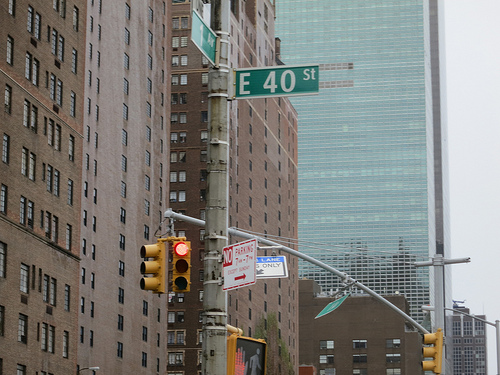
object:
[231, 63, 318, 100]
sign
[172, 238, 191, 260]
light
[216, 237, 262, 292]
sign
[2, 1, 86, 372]
building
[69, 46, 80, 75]
window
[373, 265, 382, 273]
window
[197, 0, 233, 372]
pole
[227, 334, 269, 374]
sign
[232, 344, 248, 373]
hand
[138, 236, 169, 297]
lantern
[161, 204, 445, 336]
pole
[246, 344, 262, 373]
person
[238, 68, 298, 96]
e 40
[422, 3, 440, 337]
line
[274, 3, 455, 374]
building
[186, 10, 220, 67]
sign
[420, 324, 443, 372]
light